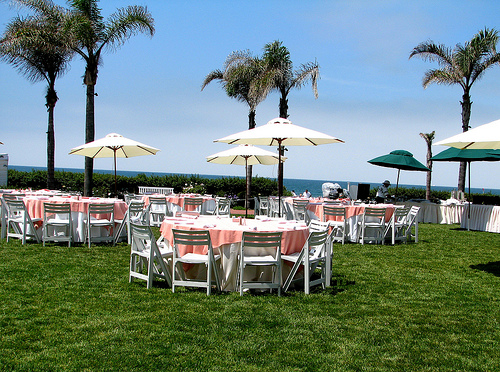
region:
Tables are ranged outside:
[7, 4, 498, 365]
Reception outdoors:
[4, 117, 498, 299]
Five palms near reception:
[0, 1, 490, 202]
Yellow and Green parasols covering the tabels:
[80, 107, 496, 183]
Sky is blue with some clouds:
[3, 6, 496, 176]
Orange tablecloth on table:
[151, 210, 317, 260]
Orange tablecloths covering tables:
[15, 176, 400, 249]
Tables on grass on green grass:
[7, 221, 497, 367]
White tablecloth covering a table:
[430, 195, 497, 230]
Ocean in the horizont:
[14, 172, 498, 200]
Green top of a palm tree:
[6, 13, 96, 84]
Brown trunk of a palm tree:
[30, 66, 72, 178]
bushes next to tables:
[20, 165, 272, 224]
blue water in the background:
[266, 167, 369, 222]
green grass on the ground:
[46, 280, 239, 361]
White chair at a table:
[133, 207, 175, 292]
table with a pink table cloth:
[155, 205, 349, 276]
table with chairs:
[110, 205, 390, 302]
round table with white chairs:
[119, 209, 358, 323]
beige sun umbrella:
[62, 119, 192, 209]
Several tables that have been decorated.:
[6, 11, 487, 329]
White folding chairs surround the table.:
[130, 190, 336, 300]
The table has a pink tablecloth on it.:
[160, 210, 310, 265]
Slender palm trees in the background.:
[10, 7, 481, 212]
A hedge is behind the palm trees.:
[2, 157, 298, 222]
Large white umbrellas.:
[70, 110, 325, 220]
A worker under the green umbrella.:
[355, 141, 422, 203]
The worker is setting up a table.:
[370, 170, 395, 201]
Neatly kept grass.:
[20, 230, 490, 367]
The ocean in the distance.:
[12, 150, 494, 200]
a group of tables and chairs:
[6, 175, 434, 312]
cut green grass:
[8, 239, 455, 370]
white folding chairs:
[113, 210, 341, 292]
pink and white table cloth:
[161, 209, 320, 265]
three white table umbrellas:
[51, 98, 338, 226]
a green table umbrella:
[373, 137, 428, 202]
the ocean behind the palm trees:
[13, 10, 498, 204]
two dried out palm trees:
[222, 41, 321, 204]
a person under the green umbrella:
[363, 147, 425, 209]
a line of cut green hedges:
[6, 155, 299, 200]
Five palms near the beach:
[1, 3, 489, 196]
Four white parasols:
[65, 114, 499, 172]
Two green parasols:
[366, 130, 498, 181]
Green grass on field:
[10, 213, 498, 363]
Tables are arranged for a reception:
[5, 175, 432, 295]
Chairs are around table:
[110, 190, 341, 293]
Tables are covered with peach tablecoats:
[15, 193, 405, 245]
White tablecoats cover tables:
[8, 190, 409, 291]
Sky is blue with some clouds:
[5, 6, 495, 182]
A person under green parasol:
[371, 169, 396, 214]